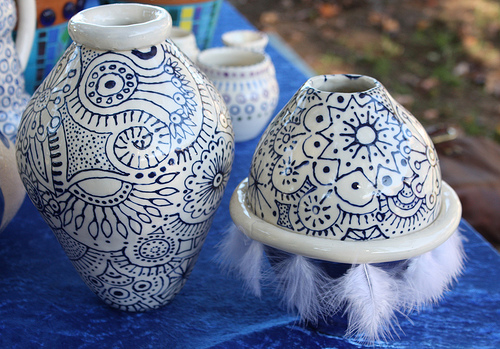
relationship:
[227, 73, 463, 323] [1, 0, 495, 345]
vase sitting on table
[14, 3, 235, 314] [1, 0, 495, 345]
vase sitting on table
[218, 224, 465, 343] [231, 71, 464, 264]
feathers on vase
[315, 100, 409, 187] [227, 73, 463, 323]
star shape on vase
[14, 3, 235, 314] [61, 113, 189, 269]
vase has designs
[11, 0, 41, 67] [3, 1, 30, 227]
handle of vase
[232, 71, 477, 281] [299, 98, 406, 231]
vase with designs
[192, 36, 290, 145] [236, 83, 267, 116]
vase with designs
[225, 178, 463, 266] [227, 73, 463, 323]
ring in middle vase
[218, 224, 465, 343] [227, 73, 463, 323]
feathers hanging from vase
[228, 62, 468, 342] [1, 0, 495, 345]
ceramic on table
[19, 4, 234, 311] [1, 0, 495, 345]
ceramic on table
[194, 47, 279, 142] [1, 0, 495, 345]
ceramic on table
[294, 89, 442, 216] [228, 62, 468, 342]
star on ceramic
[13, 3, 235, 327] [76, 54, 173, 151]
vase has swirl pattern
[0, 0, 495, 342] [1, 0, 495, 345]
table cloth on table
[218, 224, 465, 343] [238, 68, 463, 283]
feathers on vase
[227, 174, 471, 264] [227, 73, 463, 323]
whitering around vase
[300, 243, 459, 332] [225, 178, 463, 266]
feathers around ring